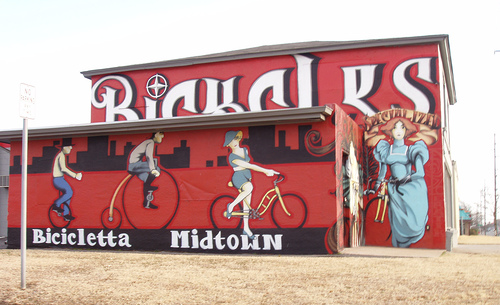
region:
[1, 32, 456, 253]
this is a house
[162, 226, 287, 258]
a word in the house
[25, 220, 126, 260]
a word in the house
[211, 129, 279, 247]
a picture of a person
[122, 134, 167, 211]
a picture of a person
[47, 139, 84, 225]
a picture of a person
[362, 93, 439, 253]
a picture of a person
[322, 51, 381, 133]
a letter on a wall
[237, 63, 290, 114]
a letter on a wall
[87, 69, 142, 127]
a letter on a wall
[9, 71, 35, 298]
the pole is silver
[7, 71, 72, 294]
the pole is silver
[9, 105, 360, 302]
drawings on the wall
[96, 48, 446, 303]
drawings on the wall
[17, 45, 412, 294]
Art painted on a building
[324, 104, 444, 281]
Art painted on a building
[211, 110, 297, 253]
Art painted on a building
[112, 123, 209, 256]
Art painted on a building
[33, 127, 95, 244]
Art painted on a building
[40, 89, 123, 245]
Art painted on a building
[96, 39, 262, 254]
Art painted on a building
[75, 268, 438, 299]
The grass is short and beige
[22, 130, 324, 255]
A drawing on the side of the building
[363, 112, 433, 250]
A woman in a blue dress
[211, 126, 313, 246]
A woman standing on a bike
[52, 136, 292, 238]
The color of the building is red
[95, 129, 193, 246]
The man is on a crazy looking bike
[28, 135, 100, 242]
The man is on a unicycle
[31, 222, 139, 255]
The word says "Bicicletta"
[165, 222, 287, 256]
The word says "Midtown"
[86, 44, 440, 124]
The word says "Bicycles"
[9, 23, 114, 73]
Sky is white color.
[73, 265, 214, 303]
Ground is brown color.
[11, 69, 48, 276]
Board is attached to the pole.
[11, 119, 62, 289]
Pole is grey color.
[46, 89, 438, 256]
Paintings are on wall.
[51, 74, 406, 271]
Letters are white color.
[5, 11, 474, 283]
Day time picture.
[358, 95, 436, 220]
Picture of woman holding umbrella.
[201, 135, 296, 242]
One woman is riding the bike in picture.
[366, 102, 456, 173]
Umbrella is brown color.